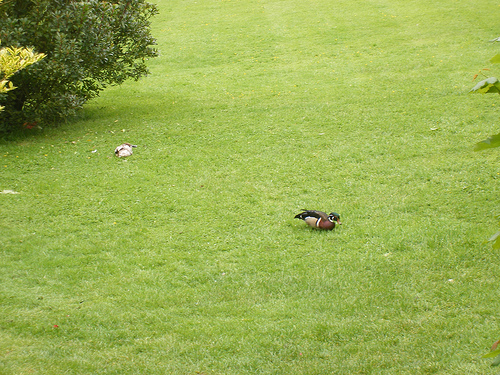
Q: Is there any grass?
A: Yes, there is grass.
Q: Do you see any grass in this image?
A: Yes, there is grass.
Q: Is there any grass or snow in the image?
A: Yes, there is grass.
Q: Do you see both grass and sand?
A: No, there is grass but no sand.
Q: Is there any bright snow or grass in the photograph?
A: Yes, there is bright grass.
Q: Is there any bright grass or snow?
A: Yes, there is bright grass.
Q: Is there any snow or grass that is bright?
A: Yes, the grass is bright.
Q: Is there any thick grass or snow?
A: Yes, there is thick grass.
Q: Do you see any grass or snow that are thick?
A: Yes, the grass is thick.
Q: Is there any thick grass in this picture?
A: Yes, there is thick grass.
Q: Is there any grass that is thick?
A: Yes, there is grass that is thick.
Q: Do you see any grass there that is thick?
A: Yes, there is grass that is thick.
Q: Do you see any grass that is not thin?
A: Yes, there is thick grass.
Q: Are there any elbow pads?
A: No, there are no elbow pads.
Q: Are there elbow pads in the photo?
A: No, there are no elbow pads.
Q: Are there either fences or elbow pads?
A: No, there are no elbow pads or fences.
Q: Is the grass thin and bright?
A: No, the grass is bright but thick.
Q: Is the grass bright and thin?
A: No, the grass is bright but thick.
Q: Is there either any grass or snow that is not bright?
A: No, there is grass but it is bright.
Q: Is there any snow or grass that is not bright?
A: No, there is grass but it is bright.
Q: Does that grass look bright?
A: Yes, the grass is bright.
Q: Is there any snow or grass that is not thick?
A: No, there is grass but it is thick.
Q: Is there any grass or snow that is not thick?
A: No, there is grass but it is thick.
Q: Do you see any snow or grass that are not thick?
A: No, there is grass but it is thick.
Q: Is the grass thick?
A: Yes, the grass is thick.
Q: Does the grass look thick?
A: Yes, the grass is thick.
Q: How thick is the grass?
A: The grass is thick.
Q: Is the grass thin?
A: No, the grass is thick.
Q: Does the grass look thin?
A: No, the grass is thick.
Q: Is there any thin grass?
A: No, there is grass but it is thick.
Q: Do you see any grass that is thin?
A: No, there is grass but it is thick.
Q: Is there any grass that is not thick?
A: No, there is grass but it is thick.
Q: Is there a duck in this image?
A: Yes, there is a duck.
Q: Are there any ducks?
A: Yes, there is a duck.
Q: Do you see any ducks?
A: Yes, there is a duck.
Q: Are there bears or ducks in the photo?
A: Yes, there is a duck.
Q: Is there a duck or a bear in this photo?
A: Yes, there is a duck.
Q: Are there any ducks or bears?
A: Yes, there is a duck.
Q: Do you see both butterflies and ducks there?
A: No, there is a duck but no butterflies.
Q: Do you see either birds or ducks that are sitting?
A: Yes, the duck is sitting.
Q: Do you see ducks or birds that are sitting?
A: Yes, the duck is sitting.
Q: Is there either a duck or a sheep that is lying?
A: Yes, the duck is lying.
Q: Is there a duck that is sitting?
A: Yes, there is a duck that is sitting.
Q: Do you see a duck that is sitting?
A: Yes, there is a duck that is sitting.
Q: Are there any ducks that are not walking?
A: Yes, there is a duck that is sitting.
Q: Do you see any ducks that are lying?
A: Yes, there is a duck that is lying.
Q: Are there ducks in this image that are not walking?
A: Yes, there is a duck that is lying.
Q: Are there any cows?
A: No, there are no cows.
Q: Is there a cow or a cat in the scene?
A: No, there are no cows or cats.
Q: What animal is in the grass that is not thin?
A: The animal is a duck.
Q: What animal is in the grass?
A: The animal is a duck.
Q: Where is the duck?
A: The duck is in the grass.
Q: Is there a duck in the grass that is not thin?
A: Yes, there is a duck in the grass.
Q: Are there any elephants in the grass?
A: No, there is a duck in the grass.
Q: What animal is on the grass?
A: The animal is a duck.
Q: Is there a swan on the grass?
A: No, there is a duck on the grass.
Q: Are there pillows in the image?
A: No, there are no pillows.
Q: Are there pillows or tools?
A: No, there are no pillows or tools.